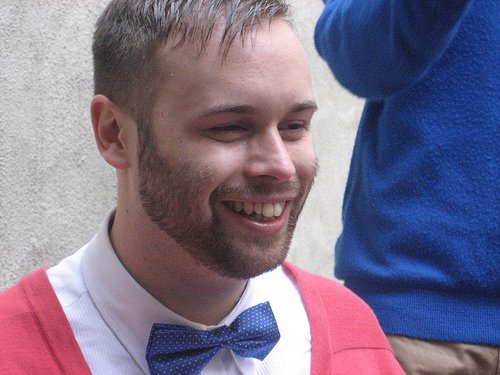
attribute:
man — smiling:
[2, 1, 409, 372]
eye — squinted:
[197, 102, 258, 142]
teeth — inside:
[222, 202, 290, 224]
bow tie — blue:
[147, 301, 281, 375]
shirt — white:
[45, 202, 312, 374]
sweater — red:
[0, 259, 406, 375]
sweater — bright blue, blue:
[313, 1, 499, 344]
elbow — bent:
[315, 3, 453, 100]